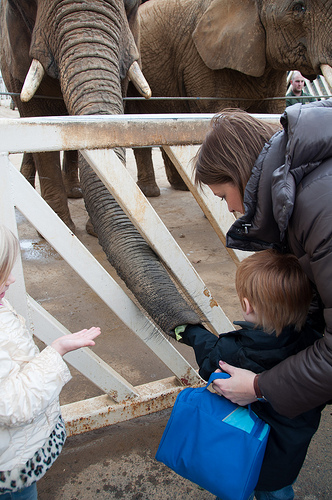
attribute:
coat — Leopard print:
[0, 305, 73, 490]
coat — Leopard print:
[269, 135, 331, 251]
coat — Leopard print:
[271, 415, 310, 478]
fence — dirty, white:
[1, 107, 295, 432]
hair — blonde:
[0, 227, 14, 286]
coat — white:
[0, 297, 68, 494]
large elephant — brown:
[0, 0, 193, 343]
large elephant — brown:
[129, 0, 331, 198]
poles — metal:
[4, 151, 243, 382]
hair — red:
[234, 249, 309, 336]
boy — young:
[174, 249, 326, 498]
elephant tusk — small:
[125, 58, 154, 100]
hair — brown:
[188, 107, 281, 216]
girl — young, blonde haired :
[0, 226, 97, 498]